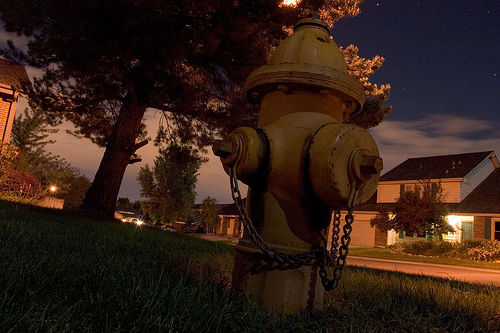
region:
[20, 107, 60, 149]
a tree in a distance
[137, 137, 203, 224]
a tree in a distance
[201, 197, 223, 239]
a tree in a distance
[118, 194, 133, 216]
a tree in a distance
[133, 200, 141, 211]
a tree in a distance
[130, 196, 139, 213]
a tree in a distance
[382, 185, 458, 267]
a tree in a distance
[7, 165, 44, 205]
a tree in a distance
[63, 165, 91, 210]
a tree in a distance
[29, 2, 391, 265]
a tree in a distance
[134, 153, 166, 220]
a tree in a distance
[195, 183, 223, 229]
a tree in a distance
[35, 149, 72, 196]
a tree in a distance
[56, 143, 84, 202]
a tree in a distance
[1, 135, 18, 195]
a tree in a distance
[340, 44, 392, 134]
a tree in a distance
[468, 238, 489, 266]
a tree in a distance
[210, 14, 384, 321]
A yellow fire hydrant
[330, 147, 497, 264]
A two-story house in the background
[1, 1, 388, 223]
A big, shadowy tree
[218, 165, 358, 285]
Chains hanging off a fire hydrant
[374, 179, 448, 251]
A small tree in front of a house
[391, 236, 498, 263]
A garden in the front yard of a house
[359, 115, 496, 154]
A cloud hanging low in the sky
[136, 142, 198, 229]
A green tree on a slope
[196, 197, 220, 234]
A green tree in front of a house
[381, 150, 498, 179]
A dark roof of a house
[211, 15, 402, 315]
a yellow fire hydrant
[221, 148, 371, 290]
a bunch of chains hanging from a fire hydrant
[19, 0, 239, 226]
a large tree with green foliage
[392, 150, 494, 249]
a two story house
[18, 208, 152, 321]
a patch of healthy green grass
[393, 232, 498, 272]
bushes and flowers in front of a house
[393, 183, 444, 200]
a set of small windows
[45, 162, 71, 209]
a bright shining light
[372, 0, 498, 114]
dark blue sky with a few stars shinning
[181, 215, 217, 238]
a black parked car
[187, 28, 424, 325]
a yellow fire hydrant.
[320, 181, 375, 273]
A chain hanging from a yellow fire hydrant.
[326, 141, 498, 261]
A two story house on a street.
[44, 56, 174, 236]
A tall tree trunk.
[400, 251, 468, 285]
A section of a street.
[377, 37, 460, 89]
A section of dark sky.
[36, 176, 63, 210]
A street light off in the distance.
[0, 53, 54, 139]
A small roofed structure.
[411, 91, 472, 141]
clouds in a dark sky.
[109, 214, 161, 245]
traffic driving down a street.